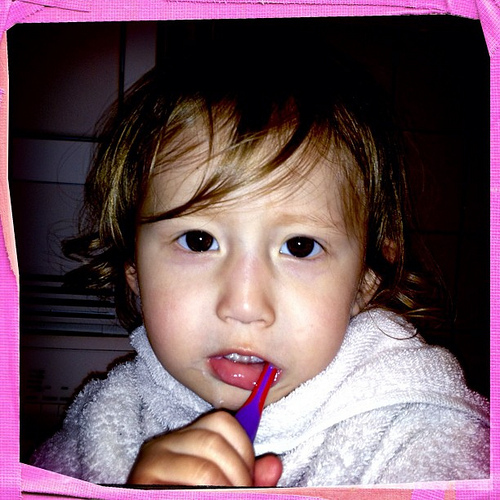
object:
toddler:
[18, 32, 490, 477]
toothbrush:
[227, 350, 286, 449]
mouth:
[211, 345, 285, 393]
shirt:
[32, 315, 489, 478]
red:
[261, 389, 268, 404]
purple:
[245, 406, 257, 429]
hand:
[123, 409, 284, 492]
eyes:
[278, 233, 328, 263]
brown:
[187, 229, 212, 253]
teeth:
[224, 352, 264, 364]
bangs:
[134, 98, 367, 223]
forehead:
[166, 114, 341, 208]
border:
[2, 1, 497, 18]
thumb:
[256, 449, 285, 485]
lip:
[206, 357, 284, 387]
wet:
[228, 367, 257, 383]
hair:
[44, 40, 460, 331]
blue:
[235, 366, 272, 439]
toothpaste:
[186, 351, 212, 380]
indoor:
[17, 39, 489, 475]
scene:
[14, 26, 484, 500]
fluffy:
[369, 340, 448, 396]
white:
[348, 352, 398, 401]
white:
[23, 139, 95, 172]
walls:
[14, 28, 141, 361]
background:
[24, 29, 495, 234]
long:
[140, 89, 323, 222]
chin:
[188, 371, 283, 418]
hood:
[351, 317, 459, 398]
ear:
[351, 228, 400, 317]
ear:
[115, 223, 140, 300]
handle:
[238, 354, 277, 439]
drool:
[194, 363, 227, 410]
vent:
[26, 265, 127, 340]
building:
[23, 21, 134, 370]